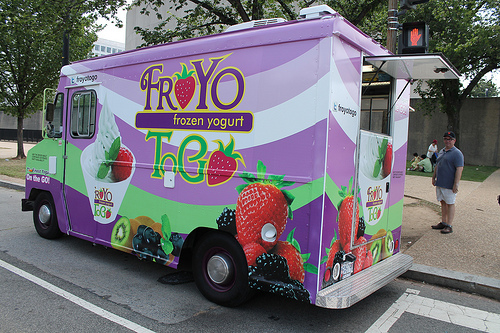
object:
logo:
[136, 51, 253, 186]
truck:
[20, 4, 461, 310]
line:
[0, 259, 152, 333]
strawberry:
[207, 150, 239, 187]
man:
[430, 131, 463, 232]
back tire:
[189, 232, 253, 306]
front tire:
[33, 194, 63, 239]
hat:
[443, 131, 456, 138]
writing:
[173, 113, 242, 129]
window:
[71, 91, 99, 137]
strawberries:
[235, 182, 304, 285]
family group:
[409, 139, 437, 173]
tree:
[316, 1, 498, 149]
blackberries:
[248, 253, 311, 305]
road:
[0, 185, 500, 332]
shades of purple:
[294, 204, 335, 250]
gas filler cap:
[260, 222, 277, 242]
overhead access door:
[365, 54, 458, 80]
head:
[444, 133, 457, 146]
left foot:
[440, 226, 452, 233]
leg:
[446, 200, 454, 226]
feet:
[432, 221, 456, 234]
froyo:
[81, 91, 135, 224]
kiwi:
[110, 217, 132, 253]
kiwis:
[371, 230, 394, 263]